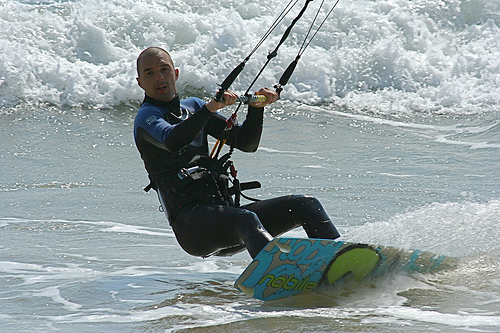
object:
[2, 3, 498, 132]
waves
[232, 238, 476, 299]
board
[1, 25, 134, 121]
wave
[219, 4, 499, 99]
wave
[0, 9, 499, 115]
waves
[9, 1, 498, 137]
wave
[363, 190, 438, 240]
wave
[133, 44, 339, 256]
male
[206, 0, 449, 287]
wind surfer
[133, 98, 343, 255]
wetsuit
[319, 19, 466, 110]
foam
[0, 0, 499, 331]
sea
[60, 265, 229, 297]
wave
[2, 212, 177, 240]
ocean wave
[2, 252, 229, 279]
ocean wave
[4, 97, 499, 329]
water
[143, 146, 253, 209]
safety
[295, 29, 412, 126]
wave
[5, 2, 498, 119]
waves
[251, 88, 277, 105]
hand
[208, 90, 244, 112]
hand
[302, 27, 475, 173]
ocean waves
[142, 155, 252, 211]
waist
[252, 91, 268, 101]
handles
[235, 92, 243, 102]
handles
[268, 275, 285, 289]
writing